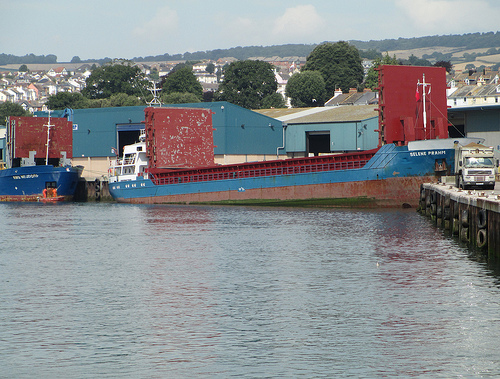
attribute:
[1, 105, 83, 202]
boat — large, blue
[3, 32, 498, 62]
trees — line of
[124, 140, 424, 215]
blue ship — large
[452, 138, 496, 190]
truck — white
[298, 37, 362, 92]
tree — large, green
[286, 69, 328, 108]
tree — green, large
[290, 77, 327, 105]
trees — green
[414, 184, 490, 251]
tires — black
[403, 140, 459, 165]
writing — white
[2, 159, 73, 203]
blue boat — large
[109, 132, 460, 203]
boat — blue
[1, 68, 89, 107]
houses — many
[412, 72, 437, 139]
mast — white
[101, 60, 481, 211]
boat — bigger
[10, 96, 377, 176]
building — blue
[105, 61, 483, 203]
ship — blue and white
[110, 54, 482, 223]
ship — heavier